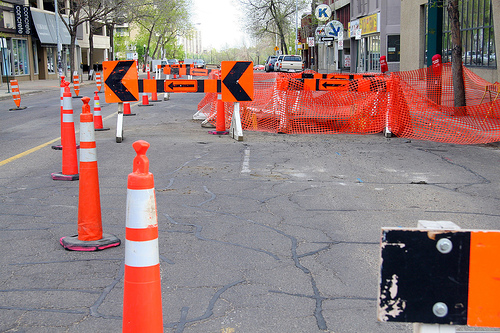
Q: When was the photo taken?
A: Daytime.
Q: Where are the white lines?
A: Pavement.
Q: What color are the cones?
A: Orange and white.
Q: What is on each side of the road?
A: Buildings.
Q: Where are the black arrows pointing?
A: Left.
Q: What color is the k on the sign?
A: Blue.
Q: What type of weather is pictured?
A: Clear.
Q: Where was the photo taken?
A: On the street.